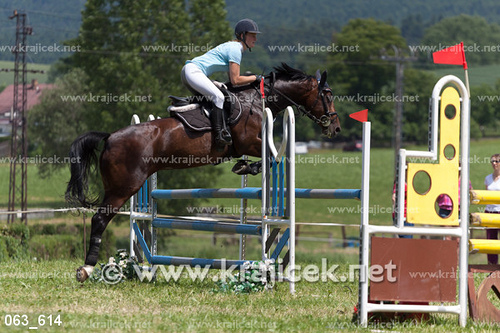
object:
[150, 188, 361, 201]
post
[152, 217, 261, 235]
post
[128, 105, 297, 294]
gate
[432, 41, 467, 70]
flag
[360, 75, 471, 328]
gate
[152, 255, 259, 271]
post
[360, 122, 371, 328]
pole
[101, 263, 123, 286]
watermark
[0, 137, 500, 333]
grass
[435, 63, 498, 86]
ground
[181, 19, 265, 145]
female rider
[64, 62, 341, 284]
horse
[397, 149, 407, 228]
pole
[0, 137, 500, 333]
ground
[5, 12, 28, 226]
pole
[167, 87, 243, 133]
saddle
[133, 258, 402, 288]
letters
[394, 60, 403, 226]
pole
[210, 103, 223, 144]
boot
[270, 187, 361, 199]
rail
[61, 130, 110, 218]
black tail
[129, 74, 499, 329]
fence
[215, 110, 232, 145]
stirrup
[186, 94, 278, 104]
english